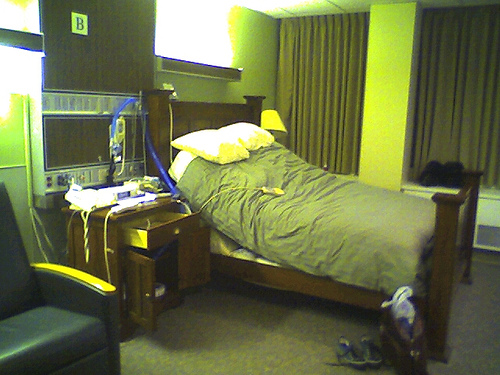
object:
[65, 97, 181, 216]
medical device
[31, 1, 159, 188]
wall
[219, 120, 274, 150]
left pillow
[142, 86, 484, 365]
bed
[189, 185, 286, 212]
remote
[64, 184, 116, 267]
phone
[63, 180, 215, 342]
desk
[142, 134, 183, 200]
breathing tube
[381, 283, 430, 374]
bag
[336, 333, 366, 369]
shoes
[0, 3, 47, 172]
lamp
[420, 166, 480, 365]
footboard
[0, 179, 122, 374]
chair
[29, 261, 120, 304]
arm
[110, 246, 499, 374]
floor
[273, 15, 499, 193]
curtain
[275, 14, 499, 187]
window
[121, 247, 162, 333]
door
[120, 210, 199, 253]
drawer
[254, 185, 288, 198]
remote unit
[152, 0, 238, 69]
light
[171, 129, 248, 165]
pillows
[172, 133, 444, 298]
sheets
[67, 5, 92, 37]
label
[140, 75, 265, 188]
headboard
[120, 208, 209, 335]
cabinet doors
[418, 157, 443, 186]
shoes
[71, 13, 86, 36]
b